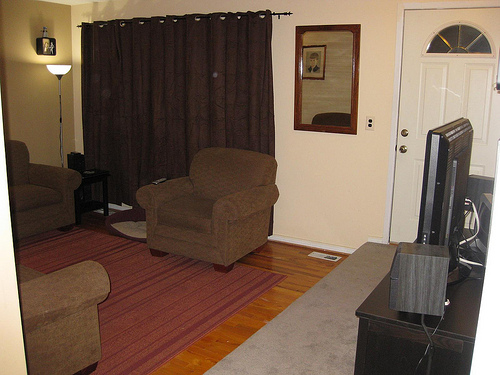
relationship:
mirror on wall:
[294, 18, 353, 160] [274, 11, 370, 236]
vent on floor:
[300, 242, 363, 271] [268, 233, 345, 303]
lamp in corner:
[49, 58, 78, 162] [62, 47, 90, 157]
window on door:
[431, 25, 497, 59] [409, 19, 499, 151]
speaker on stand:
[68, 146, 86, 175] [68, 169, 109, 218]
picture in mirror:
[304, 39, 330, 87] [294, 18, 353, 160]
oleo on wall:
[30, 31, 63, 52] [8, 3, 117, 192]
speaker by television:
[384, 229, 456, 326] [416, 115, 470, 245]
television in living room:
[416, 115, 470, 245] [47, 75, 478, 358]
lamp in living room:
[49, 58, 78, 162] [47, 75, 478, 358]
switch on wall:
[366, 113, 380, 132] [274, 11, 370, 236]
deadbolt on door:
[391, 125, 408, 152] [409, 19, 499, 151]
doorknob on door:
[395, 147, 414, 159] [409, 19, 499, 151]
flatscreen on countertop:
[416, 115, 470, 245] [357, 307, 494, 360]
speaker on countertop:
[384, 229, 456, 326] [357, 307, 494, 360]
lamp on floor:
[49, 58, 78, 162] [268, 233, 345, 303]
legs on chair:
[211, 257, 237, 277] [153, 152, 262, 246]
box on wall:
[38, 32, 82, 65] [8, 3, 117, 192]